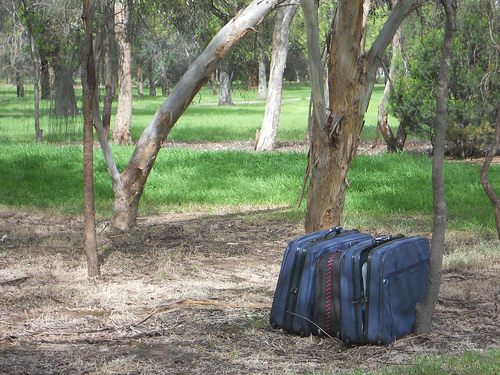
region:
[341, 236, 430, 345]
Large blue suitcase.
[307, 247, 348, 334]
Medium sized black suitcase.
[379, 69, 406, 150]
V-shaped tree trunk.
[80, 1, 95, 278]
Small straight tree trunk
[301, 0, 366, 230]
Bark-less tree trunk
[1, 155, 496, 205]
Large patch of green grass.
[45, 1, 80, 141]
Several vines hanging down from the trees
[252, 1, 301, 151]
Large tree trunk in the background.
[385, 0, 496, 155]
Tall green bushy tree.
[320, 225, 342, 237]
Blue colored suitcase handle.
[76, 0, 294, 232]
A tree on the left that resembles a wishbone.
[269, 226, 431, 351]
Blue and black luggage on the ground.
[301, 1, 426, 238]
Brown tree behind the luggage.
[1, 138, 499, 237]
Green grass behind the luggage.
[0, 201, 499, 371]
Area of dead grass, branches and leaves around luggage.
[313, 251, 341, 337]
Side of a black and red luggage bag.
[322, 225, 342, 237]
Blue handle that is sticking up on the left suitcase.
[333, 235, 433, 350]
Blue suitcase on the far right that is opened slightly.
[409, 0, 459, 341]
Tall thin gray tree to the right of the blue suitcases.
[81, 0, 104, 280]
Very thin brown tree on the left.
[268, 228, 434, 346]
Blue black and red luggage on the ground.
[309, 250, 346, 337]
Side of a black and red suitcase on the ground.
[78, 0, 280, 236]
Tree that is shaped like a wishbone.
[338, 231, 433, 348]
Blue suitcase on the right that is slightly opened.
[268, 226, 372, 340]
Blue suitcase that is sitting to the left of the black and red suitcase.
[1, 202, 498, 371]
Large brown area on the ground where the grass is dead.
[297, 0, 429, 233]
Tall brown tree behind the suitcases.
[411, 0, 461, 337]
Tall thin gray tree to the right of the luggage.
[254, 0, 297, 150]
Middle most tree trunk that has sunlight shining on it.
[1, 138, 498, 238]
Grassy area near the dead grass area.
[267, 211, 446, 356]
pieces of luggage sitting next to tree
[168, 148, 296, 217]
green grass in the woods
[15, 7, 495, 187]
trees and grass in the distance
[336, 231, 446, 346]
slightly opened luggage on ground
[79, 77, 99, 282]
slender tree trunk in the ground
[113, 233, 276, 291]
dirt ground where luggage is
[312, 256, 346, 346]
piece of black and red luggage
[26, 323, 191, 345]
twigs and sticks on the ground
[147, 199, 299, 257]
shadow casted on ground of tree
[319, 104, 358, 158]
bark coming off of tree trunk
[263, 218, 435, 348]
three suitcases on the ground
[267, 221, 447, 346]
suitcases leaning against a small tree trunk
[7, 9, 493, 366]
suitcases in a wooded area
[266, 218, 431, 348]
two blue and one black suitcase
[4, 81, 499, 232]
green grass in a wooded area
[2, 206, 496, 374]
suitcases left on a dead patch of ground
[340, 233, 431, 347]
suitcase is open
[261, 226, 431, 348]
suitcases appear to be abandoned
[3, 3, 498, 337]
many trees grow in this area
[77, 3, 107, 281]
tall thin tree trunk